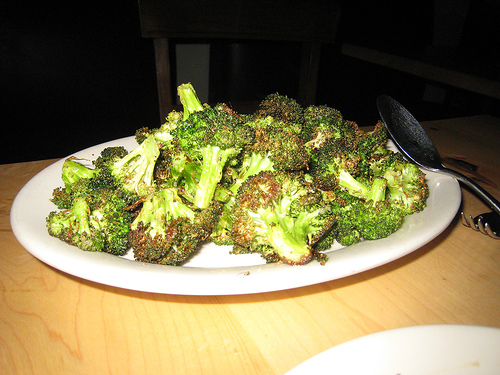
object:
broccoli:
[46, 81, 431, 267]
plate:
[7, 126, 465, 300]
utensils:
[375, 91, 500, 216]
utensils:
[457, 208, 500, 241]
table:
[2, 107, 499, 375]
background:
[1, 2, 499, 167]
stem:
[175, 81, 206, 123]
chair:
[136, 1, 341, 131]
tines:
[484, 222, 500, 241]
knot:
[439, 148, 497, 186]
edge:
[96, 255, 299, 307]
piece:
[127, 185, 224, 268]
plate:
[276, 322, 499, 374]